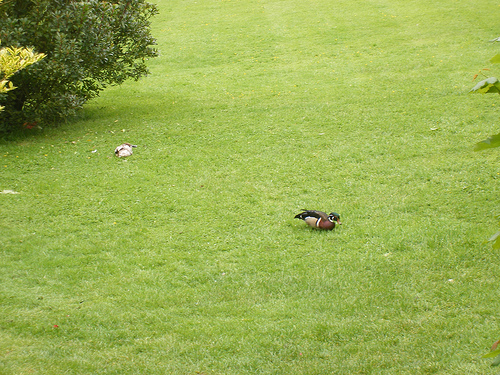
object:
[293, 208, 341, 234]
duck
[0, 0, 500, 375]
grass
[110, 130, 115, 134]
leaves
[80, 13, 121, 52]
branch